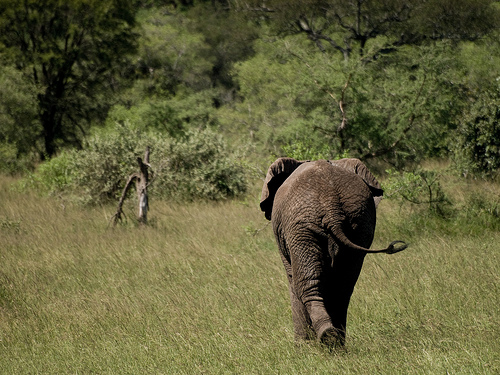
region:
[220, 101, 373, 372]
the elephant is walking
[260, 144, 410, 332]
the elephant is walking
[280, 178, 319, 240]
the elephant's skin is wrinkled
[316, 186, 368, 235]
the elephant's skin is wrinkled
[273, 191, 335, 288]
the elephant's skin is wrinkled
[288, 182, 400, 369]
the elephant's skin is wrinkled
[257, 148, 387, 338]
Elephant walking away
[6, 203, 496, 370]
Tall grassy area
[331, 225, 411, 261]
The tail of the elephant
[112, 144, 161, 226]
Tree snapped in half.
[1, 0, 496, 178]
A large amount of trees in the background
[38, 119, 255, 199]
The head of the fallen tree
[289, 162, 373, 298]
The wrinkly butt of the elephant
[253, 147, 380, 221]
The ears of the elephant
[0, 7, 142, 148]
Dark and gloomy tree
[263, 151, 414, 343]
Lonely large elephant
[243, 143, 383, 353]
gray elephant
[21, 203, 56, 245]
long green and yellow grass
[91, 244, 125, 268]
long green and yellow grass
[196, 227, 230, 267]
long green and yellow grass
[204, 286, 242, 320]
long green and yellow grass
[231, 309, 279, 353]
long green and yellow grass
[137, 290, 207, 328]
long green and yellow grass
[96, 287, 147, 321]
long green and yellow grass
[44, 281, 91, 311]
long green and yellow grass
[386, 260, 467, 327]
long green and yellow grass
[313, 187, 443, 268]
grey tail on elephant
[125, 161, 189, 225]
grey stump of tree trunk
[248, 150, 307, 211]
grey left ear of elelphant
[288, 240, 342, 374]
left rear leg of elephant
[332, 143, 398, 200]
grey right ear of elephant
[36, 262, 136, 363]
green grass on the lower left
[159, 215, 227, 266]
blowing grass on the ground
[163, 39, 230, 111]
green leaves on the trees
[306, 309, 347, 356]
left grey elephant foot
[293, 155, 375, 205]
grey back of elephant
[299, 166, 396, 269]
elephant is swinging tail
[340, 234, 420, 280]
tail is brown and bushy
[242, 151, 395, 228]
elephant has large ears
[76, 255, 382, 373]
grass is green and wavy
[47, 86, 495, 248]
green bushes in background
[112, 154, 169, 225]
small bare stump left of elephant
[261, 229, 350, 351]
elephant has brown legs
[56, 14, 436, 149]
thick green trees in background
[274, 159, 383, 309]
elephant has wrinkled skin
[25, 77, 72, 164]
thick trunk on tree on left